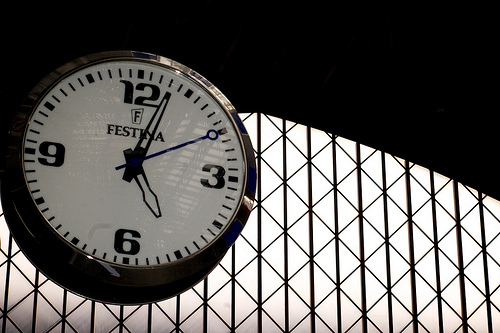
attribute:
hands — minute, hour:
[83, 106, 224, 204]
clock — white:
[45, 62, 299, 311]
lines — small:
[25, 182, 77, 231]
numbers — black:
[181, 153, 237, 185]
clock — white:
[15, 63, 259, 292]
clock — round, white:
[40, 65, 262, 256]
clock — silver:
[40, 55, 314, 326]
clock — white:
[25, 60, 275, 289]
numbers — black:
[95, 70, 178, 128]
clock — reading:
[42, 62, 314, 274]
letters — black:
[113, 101, 194, 154]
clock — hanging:
[21, 58, 309, 322]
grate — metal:
[224, 140, 423, 311]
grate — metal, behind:
[240, 142, 466, 329]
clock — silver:
[48, 52, 261, 270]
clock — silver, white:
[18, 40, 324, 330]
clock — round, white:
[56, 43, 266, 274]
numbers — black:
[99, 65, 223, 105]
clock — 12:
[51, 33, 350, 305]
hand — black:
[117, 87, 178, 189]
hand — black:
[122, 144, 167, 221]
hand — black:
[117, 130, 217, 173]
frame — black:
[1, 51, 265, 303]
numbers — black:
[40, 64, 226, 254]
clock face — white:
[6, 60, 251, 269]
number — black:
[117, 76, 165, 114]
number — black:
[33, 140, 70, 173]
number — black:
[106, 221, 144, 259]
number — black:
[195, 155, 229, 195]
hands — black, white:
[122, 87, 174, 218]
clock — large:
[1, 46, 260, 316]